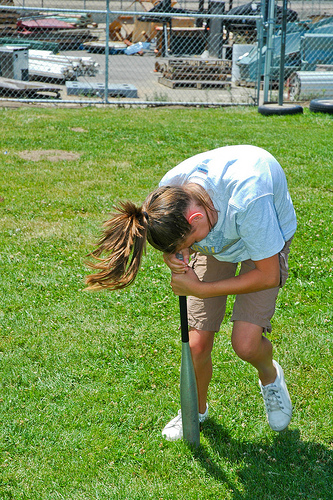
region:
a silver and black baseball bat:
[165, 248, 202, 448]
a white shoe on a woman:
[254, 358, 293, 434]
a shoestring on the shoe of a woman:
[263, 384, 283, 413]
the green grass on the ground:
[24, 398, 125, 469]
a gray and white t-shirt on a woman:
[217, 155, 269, 232]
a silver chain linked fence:
[178, 18, 222, 95]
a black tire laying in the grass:
[308, 97, 332, 116]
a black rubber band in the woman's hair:
[141, 209, 148, 220]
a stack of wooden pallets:
[161, 59, 230, 93]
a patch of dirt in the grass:
[14, 142, 81, 174]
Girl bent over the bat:
[80, 139, 313, 483]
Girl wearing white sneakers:
[249, 356, 304, 442]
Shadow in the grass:
[222, 409, 283, 482]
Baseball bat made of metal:
[157, 277, 219, 433]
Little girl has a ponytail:
[95, 173, 221, 289]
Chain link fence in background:
[60, 23, 106, 66]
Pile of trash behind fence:
[152, 39, 248, 101]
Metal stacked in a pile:
[12, 42, 98, 113]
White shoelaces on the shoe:
[265, 380, 282, 413]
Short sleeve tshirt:
[146, 146, 306, 265]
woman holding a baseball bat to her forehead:
[78, 137, 303, 450]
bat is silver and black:
[169, 251, 207, 446]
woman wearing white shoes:
[157, 354, 296, 444]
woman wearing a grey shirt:
[152, 138, 301, 263]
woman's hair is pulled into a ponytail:
[72, 176, 202, 302]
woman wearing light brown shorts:
[181, 234, 294, 335]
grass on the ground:
[17, 291, 139, 392]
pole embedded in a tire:
[259, 0, 303, 117]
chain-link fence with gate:
[0, 1, 329, 106]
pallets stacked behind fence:
[153, 52, 237, 99]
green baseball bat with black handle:
[170, 247, 203, 444]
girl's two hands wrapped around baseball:
[167, 244, 190, 291]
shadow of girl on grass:
[179, 412, 327, 494]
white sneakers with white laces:
[157, 359, 295, 440]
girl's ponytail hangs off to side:
[83, 177, 214, 292]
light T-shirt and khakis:
[154, 142, 298, 330]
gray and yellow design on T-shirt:
[186, 225, 244, 260]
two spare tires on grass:
[255, 92, 332, 117]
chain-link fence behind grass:
[1, 0, 331, 108]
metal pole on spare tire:
[273, 0, 289, 108]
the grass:
[51, 427, 81, 477]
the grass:
[44, 406, 114, 488]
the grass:
[58, 441, 113, 493]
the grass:
[71, 415, 121, 469]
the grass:
[78, 430, 155, 493]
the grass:
[108, 484, 118, 493]